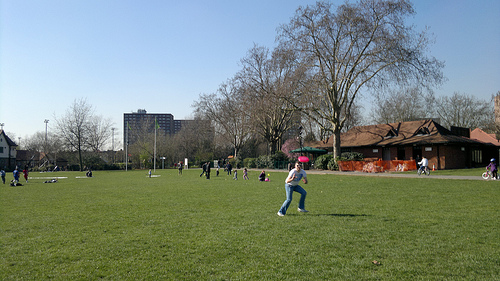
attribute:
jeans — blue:
[278, 184, 309, 210]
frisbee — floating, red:
[296, 153, 310, 164]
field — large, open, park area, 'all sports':
[0, 167, 499, 281]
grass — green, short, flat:
[6, 169, 500, 281]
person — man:
[414, 155, 432, 176]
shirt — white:
[414, 159, 430, 167]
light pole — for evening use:
[43, 118, 52, 147]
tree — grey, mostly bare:
[241, 0, 452, 185]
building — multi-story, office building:
[119, 107, 217, 171]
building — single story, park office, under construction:
[298, 112, 499, 175]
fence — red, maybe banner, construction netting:
[338, 156, 418, 175]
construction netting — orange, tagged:
[336, 156, 419, 175]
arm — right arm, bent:
[282, 170, 299, 185]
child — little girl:
[478, 155, 499, 182]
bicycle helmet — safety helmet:
[489, 158, 495, 164]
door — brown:
[410, 148, 421, 170]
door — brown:
[397, 148, 406, 162]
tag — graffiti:
[391, 162, 408, 174]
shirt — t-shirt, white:
[284, 169, 309, 186]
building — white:
[1, 127, 19, 171]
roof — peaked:
[0, 127, 19, 147]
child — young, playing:
[240, 166, 253, 182]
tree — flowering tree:
[279, 136, 305, 162]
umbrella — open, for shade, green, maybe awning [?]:
[286, 145, 327, 156]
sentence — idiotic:
[0, 278, 6, 281]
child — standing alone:
[146, 168, 154, 180]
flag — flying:
[123, 119, 135, 134]